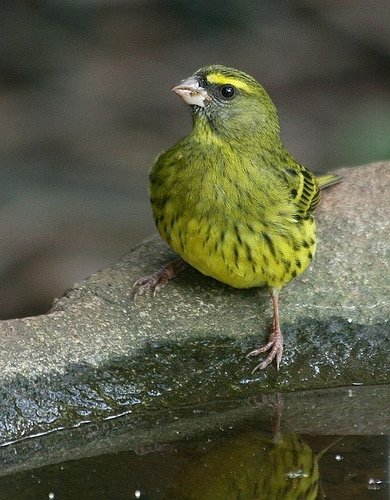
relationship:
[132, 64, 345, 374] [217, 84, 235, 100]
bird has an eye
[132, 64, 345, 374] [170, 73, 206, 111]
bird has a beak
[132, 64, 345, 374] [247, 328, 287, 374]
bird has a foot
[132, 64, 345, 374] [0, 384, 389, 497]
bird close to water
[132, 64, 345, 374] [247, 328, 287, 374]
bird has foot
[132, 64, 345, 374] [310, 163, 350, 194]
bird has a tail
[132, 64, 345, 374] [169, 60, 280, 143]
bird has a head